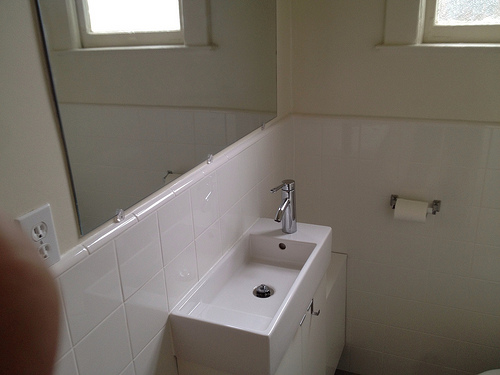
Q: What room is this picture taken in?
A: Bathroom.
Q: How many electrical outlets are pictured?
A: One.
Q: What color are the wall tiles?
A: White.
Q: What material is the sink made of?
A: Porcelain.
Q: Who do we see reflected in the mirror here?
A: No one.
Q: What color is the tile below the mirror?
A: White.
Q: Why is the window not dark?
A: It's light outside.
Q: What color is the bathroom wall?
A: White.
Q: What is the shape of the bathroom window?
A: Rectangle.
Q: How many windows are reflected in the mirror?
A: 1.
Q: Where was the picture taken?
A: In a bathroom.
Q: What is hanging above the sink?
A: A mirror.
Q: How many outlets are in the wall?
A: 2.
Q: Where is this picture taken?
A: A bathroom.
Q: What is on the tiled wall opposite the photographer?
A: Toilet paper.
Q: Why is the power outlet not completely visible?
A: The photographer's finger is blocking it.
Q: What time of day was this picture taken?
A: Day time.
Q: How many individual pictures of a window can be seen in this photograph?
A: Two.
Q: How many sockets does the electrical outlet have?
A: Two.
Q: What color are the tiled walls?
A: White.